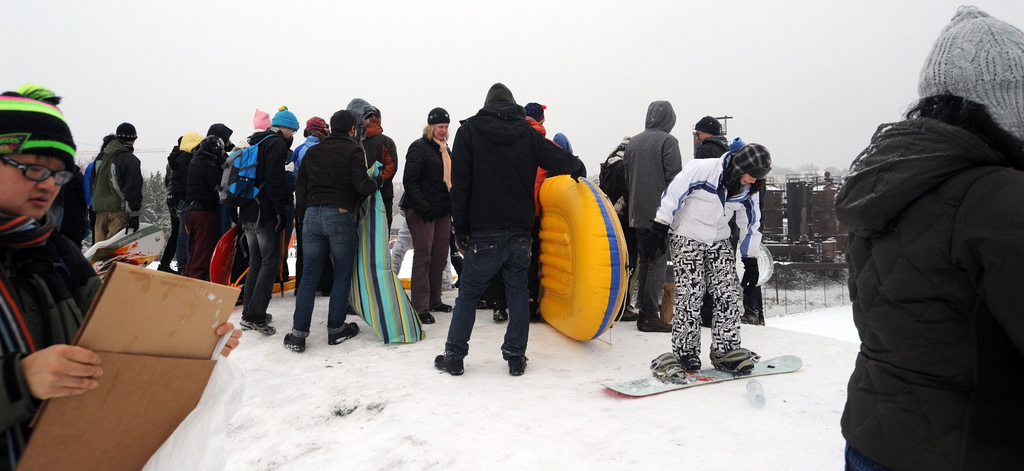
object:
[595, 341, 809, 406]
snowboard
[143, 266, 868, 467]
snow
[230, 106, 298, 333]
child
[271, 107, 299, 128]
cap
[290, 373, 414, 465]
footprints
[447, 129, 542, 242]
jacket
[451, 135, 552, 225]
jacket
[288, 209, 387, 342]
jeans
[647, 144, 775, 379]
boy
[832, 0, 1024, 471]
person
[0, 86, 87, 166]
black cap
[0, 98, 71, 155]
green/pink stripes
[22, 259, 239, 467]
box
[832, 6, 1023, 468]
girl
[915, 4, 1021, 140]
beanie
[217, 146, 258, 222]
blue backpack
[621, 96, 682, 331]
man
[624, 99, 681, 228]
coat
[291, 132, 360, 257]
girl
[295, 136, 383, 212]
coat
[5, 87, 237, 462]
man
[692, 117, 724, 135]
hat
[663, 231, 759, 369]
pants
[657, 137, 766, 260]
white coat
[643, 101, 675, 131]
hood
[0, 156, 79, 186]
glasses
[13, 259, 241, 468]
cardboard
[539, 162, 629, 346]
raft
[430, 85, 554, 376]
man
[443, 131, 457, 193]
scarf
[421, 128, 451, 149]
woman's neck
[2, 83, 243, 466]
boy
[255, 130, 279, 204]
strap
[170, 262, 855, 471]
ground